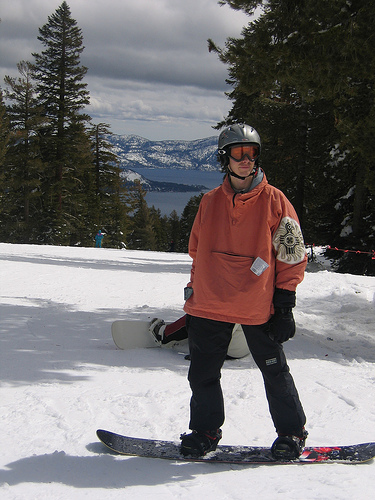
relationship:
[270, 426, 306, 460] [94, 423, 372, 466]
boot on snowboard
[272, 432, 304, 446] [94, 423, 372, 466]
binder on snowboard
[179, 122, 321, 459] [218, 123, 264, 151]
man wearing helmet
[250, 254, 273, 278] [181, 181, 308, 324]
ticket on jacket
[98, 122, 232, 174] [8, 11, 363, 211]
mountains in distance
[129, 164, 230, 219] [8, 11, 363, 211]
lake in distance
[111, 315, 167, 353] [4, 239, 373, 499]
snowboard in snow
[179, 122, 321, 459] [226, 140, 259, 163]
man wearing goggles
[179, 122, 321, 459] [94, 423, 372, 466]
man standing on snowboard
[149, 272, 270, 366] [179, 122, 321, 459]
person sitting behind man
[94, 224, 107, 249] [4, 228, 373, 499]
person walking up hill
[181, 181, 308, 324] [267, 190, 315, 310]
jacket has sleeve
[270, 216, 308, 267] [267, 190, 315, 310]
graphic on sleeve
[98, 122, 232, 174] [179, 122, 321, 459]
mountains behind man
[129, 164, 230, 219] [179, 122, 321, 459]
lake behind man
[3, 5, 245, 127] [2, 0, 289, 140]
clouds in sky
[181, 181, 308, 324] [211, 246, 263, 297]
jacket has pocket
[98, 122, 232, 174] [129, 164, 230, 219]
mountains surrounding lake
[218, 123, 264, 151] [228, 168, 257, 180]
helmet has chin strap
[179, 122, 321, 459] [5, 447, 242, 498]
man has shadow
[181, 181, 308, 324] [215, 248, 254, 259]
jacket has zipper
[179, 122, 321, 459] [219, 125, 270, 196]
man has head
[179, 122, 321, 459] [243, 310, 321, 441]
man has leg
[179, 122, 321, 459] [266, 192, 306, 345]
man has arm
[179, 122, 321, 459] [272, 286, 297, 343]
man has glove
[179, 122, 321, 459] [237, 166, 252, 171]
man has mouth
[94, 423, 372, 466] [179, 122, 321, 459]
snowboard under man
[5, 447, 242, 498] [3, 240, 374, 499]
shadow on ground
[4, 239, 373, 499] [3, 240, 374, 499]
snow on ground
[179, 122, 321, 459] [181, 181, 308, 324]
man wearing jacket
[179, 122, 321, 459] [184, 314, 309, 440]
man wearing pants